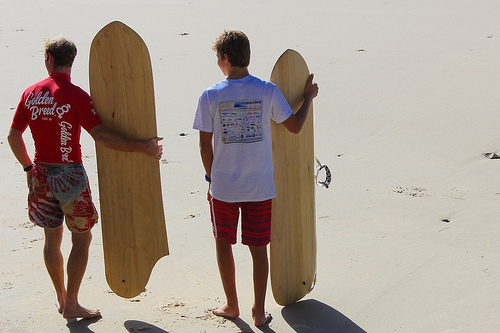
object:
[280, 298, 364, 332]
shadow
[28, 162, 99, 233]
pants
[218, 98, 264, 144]
design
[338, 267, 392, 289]
beach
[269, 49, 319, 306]
board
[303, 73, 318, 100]
hand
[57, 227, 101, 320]
legs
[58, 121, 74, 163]
part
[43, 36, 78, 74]
head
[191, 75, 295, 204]
shirt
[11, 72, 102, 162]
red shirt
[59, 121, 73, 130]
letter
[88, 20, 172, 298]
board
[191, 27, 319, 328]
man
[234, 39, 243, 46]
hair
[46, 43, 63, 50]
hair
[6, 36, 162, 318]
man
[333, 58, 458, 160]
ground